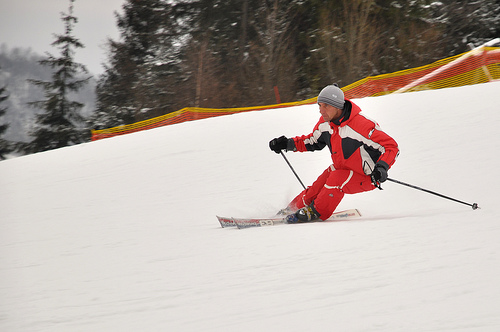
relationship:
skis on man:
[429, 172, 484, 217] [268, 92, 413, 224]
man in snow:
[268, 92, 413, 224] [93, 194, 186, 236]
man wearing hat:
[268, 92, 413, 224] [321, 85, 355, 104]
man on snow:
[268, 92, 413, 224] [93, 194, 186, 236]